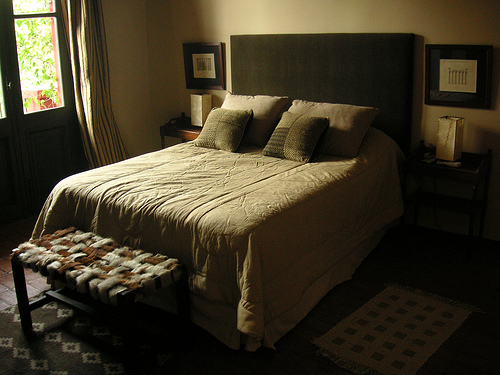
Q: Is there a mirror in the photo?
A: No, there are no mirrors.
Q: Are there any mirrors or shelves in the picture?
A: No, there are no mirrors or shelves.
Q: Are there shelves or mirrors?
A: No, there are no mirrors or shelves.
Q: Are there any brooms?
A: No, there are no brooms.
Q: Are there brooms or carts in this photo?
A: No, there are no brooms or carts.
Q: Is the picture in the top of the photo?
A: Yes, the picture is in the top of the image.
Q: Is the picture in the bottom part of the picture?
A: No, the picture is in the top of the image.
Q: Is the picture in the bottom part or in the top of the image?
A: The picture is in the top of the image.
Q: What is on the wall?
A: The picture is on the wall.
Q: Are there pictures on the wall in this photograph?
A: Yes, there is a picture on the wall.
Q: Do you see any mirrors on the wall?
A: No, there is a picture on the wall.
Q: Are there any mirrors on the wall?
A: No, there is a picture on the wall.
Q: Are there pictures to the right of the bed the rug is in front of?
A: Yes, there is a picture to the right of the bed.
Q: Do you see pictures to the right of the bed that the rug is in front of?
A: Yes, there is a picture to the right of the bed.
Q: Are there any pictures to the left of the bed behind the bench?
A: No, the picture is to the right of the bed.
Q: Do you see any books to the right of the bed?
A: No, there is a picture to the right of the bed.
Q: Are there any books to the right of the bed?
A: No, there is a picture to the right of the bed.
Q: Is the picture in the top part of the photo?
A: Yes, the picture is in the top of the image.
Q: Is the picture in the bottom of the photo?
A: No, the picture is in the top of the image.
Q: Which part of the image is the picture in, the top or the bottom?
A: The picture is in the top of the image.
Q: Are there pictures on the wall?
A: Yes, there is a picture on the wall.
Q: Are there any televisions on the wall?
A: No, there is a picture on the wall.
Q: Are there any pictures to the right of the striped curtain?
A: Yes, there is a picture to the right of the curtain.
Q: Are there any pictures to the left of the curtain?
A: No, the picture is to the right of the curtain.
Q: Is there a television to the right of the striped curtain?
A: No, there is a picture to the right of the curtain.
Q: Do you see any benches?
A: Yes, there is a bench.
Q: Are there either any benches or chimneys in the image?
A: Yes, there is a bench.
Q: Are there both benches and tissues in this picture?
A: No, there is a bench but no tissues.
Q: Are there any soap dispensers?
A: No, there are no soap dispensers.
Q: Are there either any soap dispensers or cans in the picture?
A: No, there are no soap dispensers or cans.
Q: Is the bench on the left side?
A: Yes, the bench is on the left of the image.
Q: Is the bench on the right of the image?
A: No, the bench is on the left of the image.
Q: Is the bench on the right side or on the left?
A: The bench is on the left of the image.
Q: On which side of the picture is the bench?
A: The bench is on the left of the image.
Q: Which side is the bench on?
A: The bench is on the left of the image.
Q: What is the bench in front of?
A: The bench is in front of the bed.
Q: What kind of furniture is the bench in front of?
A: The bench is in front of the bed.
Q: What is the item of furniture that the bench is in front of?
A: The piece of furniture is a bed.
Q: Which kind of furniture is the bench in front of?
A: The bench is in front of the bed.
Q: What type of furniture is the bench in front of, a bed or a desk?
A: The bench is in front of a bed.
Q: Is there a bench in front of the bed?
A: Yes, there is a bench in front of the bed.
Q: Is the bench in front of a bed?
A: Yes, the bench is in front of a bed.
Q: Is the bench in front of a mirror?
A: No, the bench is in front of a bed.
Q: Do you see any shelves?
A: No, there are no shelves.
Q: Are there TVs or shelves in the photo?
A: No, there are no shelves or tvs.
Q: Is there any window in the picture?
A: Yes, there is a window.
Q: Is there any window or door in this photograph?
A: Yes, there is a window.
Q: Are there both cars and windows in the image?
A: No, there is a window but no cars.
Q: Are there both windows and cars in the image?
A: No, there is a window but no cars.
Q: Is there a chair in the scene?
A: No, there are no chairs.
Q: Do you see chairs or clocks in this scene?
A: No, there are no chairs or clocks.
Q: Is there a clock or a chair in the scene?
A: No, there are no chairs or clocks.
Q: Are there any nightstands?
A: Yes, there is a nightstand.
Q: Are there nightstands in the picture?
A: Yes, there is a nightstand.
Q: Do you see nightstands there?
A: Yes, there is a nightstand.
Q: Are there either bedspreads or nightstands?
A: Yes, there is a nightstand.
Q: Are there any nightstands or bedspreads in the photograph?
A: Yes, there is a nightstand.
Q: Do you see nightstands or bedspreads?
A: Yes, there is a nightstand.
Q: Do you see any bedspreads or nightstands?
A: Yes, there is a nightstand.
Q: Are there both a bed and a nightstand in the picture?
A: Yes, there are both a nightstand and a bed.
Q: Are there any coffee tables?
A: No, there are no coffee tables.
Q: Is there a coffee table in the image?
A: No, there are no coffee tables.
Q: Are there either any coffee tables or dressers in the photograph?
A: No, there are no coffee tables or dressers.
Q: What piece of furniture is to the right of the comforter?
A: The piece of furniture is a nightstand.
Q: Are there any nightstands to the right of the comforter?
A: Yes, there is a nightstand to the right of the comforter.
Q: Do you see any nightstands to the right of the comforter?
A: Yes, there is a nightstand to the right of the comforter.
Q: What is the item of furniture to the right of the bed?
A: The piece of furniture is a nightstand.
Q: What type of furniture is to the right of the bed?
A: The piece of furniture is a nightstand.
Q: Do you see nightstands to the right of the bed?
A: Yes, there is a nightstand to the right of the bed.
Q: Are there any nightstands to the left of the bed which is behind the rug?
A: No, the nightstand is to the right of the bed.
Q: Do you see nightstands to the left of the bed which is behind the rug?
A: No, the nightstand is to the right of the bed.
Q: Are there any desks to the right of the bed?
A: No, there is a nightstand to the right of the bed.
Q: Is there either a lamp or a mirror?
A: Yes, there is a lamp.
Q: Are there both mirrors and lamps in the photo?
A: No, there is a lamp but no mirrors.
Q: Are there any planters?
A: No, there are no planters.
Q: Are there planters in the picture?
A: No, there are no planters.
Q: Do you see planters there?
A: No, there are no planters.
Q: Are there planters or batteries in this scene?
A: No, there are no planters or batteries.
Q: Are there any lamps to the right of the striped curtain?
A: Yes, there is a lamp to the right of the curtain.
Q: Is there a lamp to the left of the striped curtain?
A: No, the lamp is to the right of the curtain.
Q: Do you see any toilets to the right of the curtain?
A: No, there is a lamp to the right of the curtain.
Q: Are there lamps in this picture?
A: Yes, there is a lamp.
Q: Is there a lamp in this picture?
A: Yes, there is a lamp.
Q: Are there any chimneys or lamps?
A: Yes, there is a lamp.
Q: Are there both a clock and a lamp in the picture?
A: No, there is a lamp but no clocks.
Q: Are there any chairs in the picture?
A: No, there are no chairs.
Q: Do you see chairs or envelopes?
A: No, there are no chairs or envelopes.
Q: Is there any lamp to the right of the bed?
A: Yes, there is a lamp to the right of the bed.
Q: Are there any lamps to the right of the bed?
A: Yes, there is a lamp to the right of the bed.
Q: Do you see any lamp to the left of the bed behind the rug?
A: No, the lamp is to the right of the bed.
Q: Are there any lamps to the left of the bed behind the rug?
A: No, the lamp is to the right of the bed.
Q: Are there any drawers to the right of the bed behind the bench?
A: No, there is a lamp to the right of the bed.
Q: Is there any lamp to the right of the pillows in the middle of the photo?
A: Yes, there is a lamp to the right of the pillows.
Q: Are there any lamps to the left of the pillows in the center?
A: No, the lamp is to the right of the pillows.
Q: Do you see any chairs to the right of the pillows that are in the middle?
A: No, there is a lamp to the right of the pillows.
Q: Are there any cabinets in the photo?
A: No, there are no cabinets.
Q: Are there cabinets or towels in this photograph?
A: No, there are no cabinets or towels.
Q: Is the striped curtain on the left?
A: Yes, the curtain is on the left of the image.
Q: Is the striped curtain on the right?
A: No, the curtain is on the left of the image.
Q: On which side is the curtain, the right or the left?
A: The curtain is on the left of the image.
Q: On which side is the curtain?
A: The curtain is on the left of the image.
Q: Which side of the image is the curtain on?
A: The curtain is on the left of the image.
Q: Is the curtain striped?
A: Yes, the curtain is striped.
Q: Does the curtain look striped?
A: Yes, the curtain is striped.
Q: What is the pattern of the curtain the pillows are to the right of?
A: The curtain is striped.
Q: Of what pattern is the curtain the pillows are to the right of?
A: The curtain is striped.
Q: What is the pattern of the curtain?
A: The curtain is striped.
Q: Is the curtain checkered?
A: No, the curtain is striped.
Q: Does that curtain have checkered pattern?
A: No, the curtain is striped.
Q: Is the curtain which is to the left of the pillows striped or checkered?
A: The curtain is striped.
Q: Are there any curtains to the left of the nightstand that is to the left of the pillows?
A: Yes, there is a curtain to the left of the nightstand.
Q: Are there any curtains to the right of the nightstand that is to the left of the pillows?
A: No, the curtain is to the left of the nightstand.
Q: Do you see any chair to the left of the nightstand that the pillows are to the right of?
A: No, there is a curtain to the left of the nightstand.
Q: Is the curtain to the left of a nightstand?
A: Yes, the curtain is to the left of a nightstand.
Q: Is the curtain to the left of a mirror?
A: No, the curtain is to the left of a nightstand.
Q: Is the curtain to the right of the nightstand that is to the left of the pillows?
A: No, the curtain is to the left of the nightstand.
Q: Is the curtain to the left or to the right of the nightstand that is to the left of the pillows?
A: The curtain is to the left of the nightstand.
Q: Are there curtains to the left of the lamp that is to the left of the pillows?
A: Yes, there is a curtain to the left of the lamp.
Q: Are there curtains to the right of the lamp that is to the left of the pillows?
A: No, the curtain is to the left of the lamp.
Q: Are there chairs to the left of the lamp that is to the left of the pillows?
A: No, there is a curtain to the left of the lamp.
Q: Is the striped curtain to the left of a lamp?
A: Yes, the curtain is to the left of a lamp.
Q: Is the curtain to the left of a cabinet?
A: No, the curtain is to the left of a lamp.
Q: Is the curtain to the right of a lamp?
A: No, the curtain is to the left of a lamp.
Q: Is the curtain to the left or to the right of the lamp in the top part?
A: The curtain is to the left of the lamp.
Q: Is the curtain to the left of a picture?
A: Yes, the curtain is to the left of a picture.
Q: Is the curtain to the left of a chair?
A: No, the curtain is to the left of a picture.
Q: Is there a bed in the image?
A: Yes, there is a bed.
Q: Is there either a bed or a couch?
A: Yes, there is a bed.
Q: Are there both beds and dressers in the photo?
A: No, there is a bed but no dressers.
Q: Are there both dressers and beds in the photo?
A: No, there is a bed but no dressers.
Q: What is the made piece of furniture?
A: The piece of furniture is a bed.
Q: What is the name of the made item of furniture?
A: The piece of furniture is a bed.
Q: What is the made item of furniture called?
A: The piece of furniture is a bed.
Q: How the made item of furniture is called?
A: The piece of furniture is a bed.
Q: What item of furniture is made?
A: The piece of furniture is a bed.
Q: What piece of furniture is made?
A: The piece of furniture is a bed.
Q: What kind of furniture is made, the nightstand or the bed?
A: The bed is made.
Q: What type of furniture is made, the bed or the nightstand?
A: The bed is made.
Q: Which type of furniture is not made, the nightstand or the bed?
A: The nightstand is not made.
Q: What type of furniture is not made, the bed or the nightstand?
A: The nightstand is not made.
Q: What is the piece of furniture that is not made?
A: The piece of furniture is a nightstand.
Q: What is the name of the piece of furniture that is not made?
A: The piece of furniture is a nightstand.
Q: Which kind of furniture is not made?
A: The furniture is a nightstand.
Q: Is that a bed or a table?
A: That is a bed.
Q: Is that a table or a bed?
A: That is a bed.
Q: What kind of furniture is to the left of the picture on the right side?
A: The piece of furniture is a bed.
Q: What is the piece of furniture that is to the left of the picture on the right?
A: The piece of furniture is a bed.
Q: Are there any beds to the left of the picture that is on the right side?
A: Yes, there is a bed to the left of the picture.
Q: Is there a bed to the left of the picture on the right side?
A: Yes, there is a bed to the left of the picture.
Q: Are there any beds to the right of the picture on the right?
A: No, the bed is to the left of the picture.